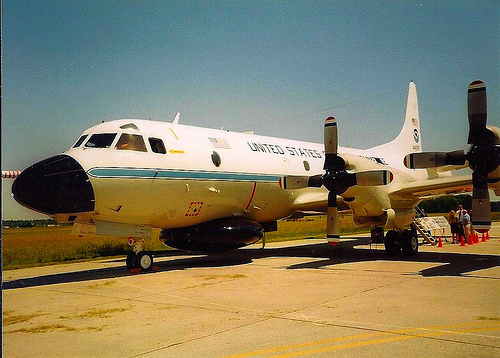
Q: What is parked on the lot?
A: Airplane.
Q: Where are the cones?
A: Ground.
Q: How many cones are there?
A: Six.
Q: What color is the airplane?
A: White.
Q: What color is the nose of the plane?
A: Black.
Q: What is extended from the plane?
A: Stairs.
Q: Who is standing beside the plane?
A: People.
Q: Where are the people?
A: Near the plane.